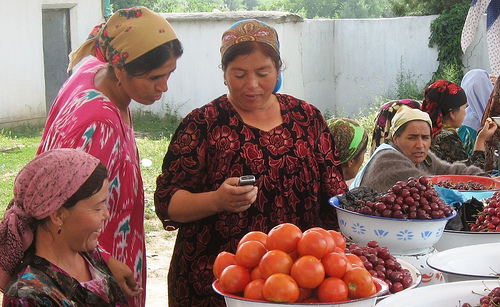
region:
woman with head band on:
[196, 215, 391, 295]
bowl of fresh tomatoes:
[205, 225, 375, 281]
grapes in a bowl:
[375, 170, 456, 221]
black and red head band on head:
[420, 67, 468, 103]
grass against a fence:
[1, 110, 29, 157]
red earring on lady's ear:
[56, 212, 66, 238]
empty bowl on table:
[420, 233, 495, 278]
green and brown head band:
[325, 100, 367, 167]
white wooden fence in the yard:
[310, 10, 421, 87]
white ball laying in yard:
[140, 154, 163, 175]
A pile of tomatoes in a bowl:
[205, 220, 391, 302]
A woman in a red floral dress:
[152, 12, 369, 299]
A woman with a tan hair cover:
[384, 103, 434, 163]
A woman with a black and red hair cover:
[417, 77, 494, 168]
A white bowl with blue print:
[325, 185, 459, 250]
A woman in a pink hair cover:
[0, 147, 116, 296]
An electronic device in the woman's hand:
[219, 170, 261, 210]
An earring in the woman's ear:
[114, 77, 126, 87]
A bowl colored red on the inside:
[426, 170, 498, 205]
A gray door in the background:
[33, 3, 95, 130]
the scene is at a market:
[4, 28, 496, 305]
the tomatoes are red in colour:
[208, 226, 374, 304]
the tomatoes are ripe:
[213, 220, 370, 302]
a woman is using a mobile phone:
[180, 15, 342, 242]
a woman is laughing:
[1, 138, 161, 305]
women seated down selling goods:
[301, 61, 494, 154]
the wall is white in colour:
[299, 32, 418, 95]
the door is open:
[41, 3, 76, 103]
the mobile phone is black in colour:
[185, 170, 297, 223]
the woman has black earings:
[3, 139, 117, 305]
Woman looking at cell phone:
[152, 21, 345, 305]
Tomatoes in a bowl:
[210, 221, 381, 305]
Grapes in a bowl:
[329, 174, 453, 254]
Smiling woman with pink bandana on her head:
[0, 147, 110, 281]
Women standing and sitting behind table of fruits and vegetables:
[2, 7, 497, 302]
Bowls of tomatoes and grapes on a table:
[208, 177, 498, 304]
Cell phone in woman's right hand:
[220, 167, 260, 213]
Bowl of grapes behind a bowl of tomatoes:
[344, 238, 417, 293]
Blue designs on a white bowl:
[331, 199, 452, 256]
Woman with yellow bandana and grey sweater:
[363, 102, 474, 187]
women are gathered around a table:
[8, 8, 498, 304]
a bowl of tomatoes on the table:
[207, 208, 387, 305]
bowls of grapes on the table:
[327, 166, 499, 256]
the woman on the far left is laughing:
[3, 141, 133, 305]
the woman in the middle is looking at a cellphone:
[156, 13, 363, 305]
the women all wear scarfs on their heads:
[10, 18, 497, 305]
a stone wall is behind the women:
[11, 0, 498, 122]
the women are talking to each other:
[0, 12, 499, 291]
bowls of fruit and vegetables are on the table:
[220, 156, 498, 300]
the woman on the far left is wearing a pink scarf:
[15, 149, 150, 305]